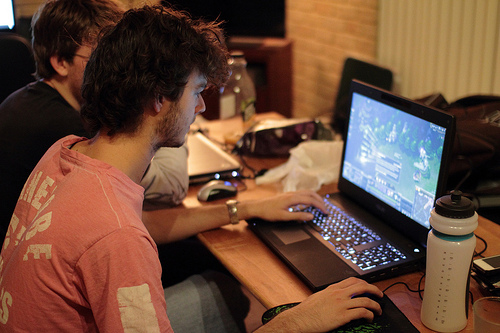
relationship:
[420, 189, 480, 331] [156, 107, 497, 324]
bottle on desk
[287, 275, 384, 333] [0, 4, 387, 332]
hand on man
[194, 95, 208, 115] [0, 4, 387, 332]
nose on man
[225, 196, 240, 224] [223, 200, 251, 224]
watch on wrist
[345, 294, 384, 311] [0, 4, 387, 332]
finger on man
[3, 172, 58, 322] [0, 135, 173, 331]
letters on shirt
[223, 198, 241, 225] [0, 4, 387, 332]
watch on man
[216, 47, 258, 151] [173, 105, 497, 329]
bottle on table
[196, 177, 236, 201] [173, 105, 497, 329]
computer mouse on table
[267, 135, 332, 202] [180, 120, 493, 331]
paper on table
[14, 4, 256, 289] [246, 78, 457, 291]
man on laptop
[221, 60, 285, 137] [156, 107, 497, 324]
bottle sitting on desk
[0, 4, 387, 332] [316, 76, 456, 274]
man using laptop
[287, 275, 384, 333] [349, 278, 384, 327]
hand on mouse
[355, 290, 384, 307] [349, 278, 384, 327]
hand on mouse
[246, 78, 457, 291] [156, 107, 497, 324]
laptop sitting on desk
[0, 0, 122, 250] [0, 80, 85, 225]
man wearing black shirt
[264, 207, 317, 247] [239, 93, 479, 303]
trackpad on laptop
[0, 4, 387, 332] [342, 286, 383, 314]
man has finger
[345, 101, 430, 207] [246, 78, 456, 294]
screen on laptop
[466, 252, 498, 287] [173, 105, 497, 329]
phone laying on table